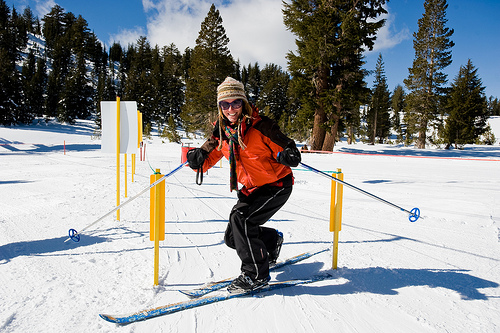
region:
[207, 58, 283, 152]
the woman is wearing glasses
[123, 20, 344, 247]
a woman is skiing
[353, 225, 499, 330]
a shadow of a woman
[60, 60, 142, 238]
signs on yellow poles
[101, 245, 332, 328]
the woman is on blue skis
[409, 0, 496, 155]
tall green trees in the background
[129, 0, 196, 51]
white clouds in the sky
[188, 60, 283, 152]
a woman wearing a hat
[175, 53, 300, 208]
the woman's jacket is orange and black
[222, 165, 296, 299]
the woman is wearing black pants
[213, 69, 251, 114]
tan beenie on head of female skier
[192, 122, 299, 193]
red and black jacket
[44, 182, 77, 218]
white snow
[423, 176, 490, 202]
white snow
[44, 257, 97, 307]
white snow on ground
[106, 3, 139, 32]
white clouds in blue sky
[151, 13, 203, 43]
white clouds in blue sky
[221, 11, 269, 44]
white clouds in blue sky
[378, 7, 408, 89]
white clouds in blue sky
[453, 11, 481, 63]
white clouds in blue sky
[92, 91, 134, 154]
white and yellow sign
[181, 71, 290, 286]
female skier in white snow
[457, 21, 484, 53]
white clouds in blue sky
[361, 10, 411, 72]
white clouds in blue sky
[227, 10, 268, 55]
white clouds in blue sky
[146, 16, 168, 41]
white clouds in blue sky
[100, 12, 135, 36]
white clouds in blue sky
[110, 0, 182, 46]
white clouds in blue sky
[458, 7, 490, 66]
white clouds in blue sky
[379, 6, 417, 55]
white clouds in blue sky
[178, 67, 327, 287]
female skier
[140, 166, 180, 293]
yellow post in snow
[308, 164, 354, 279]
yellow post in snow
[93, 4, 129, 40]
white clouds in blue sky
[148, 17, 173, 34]
white clouds in blue sky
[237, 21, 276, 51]
white clouds in blue sky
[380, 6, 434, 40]
white clouds in blue sky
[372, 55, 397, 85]
white clouds in blue sky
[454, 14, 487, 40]
white clouds in blue sky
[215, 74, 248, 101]
a knitted ski hat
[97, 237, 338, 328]
the girl's blue skis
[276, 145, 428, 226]
a blue ski pole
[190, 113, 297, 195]
an ornage and black ski jacket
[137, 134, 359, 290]
a marked off lane approaching the ski lift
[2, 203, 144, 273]
shadow from the ski lift chair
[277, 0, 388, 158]
tall evergreen trees in the background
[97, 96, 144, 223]
signs on yellow poles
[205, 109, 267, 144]
the girl's multi-colored scarf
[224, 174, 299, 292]
the girl's black ski pants